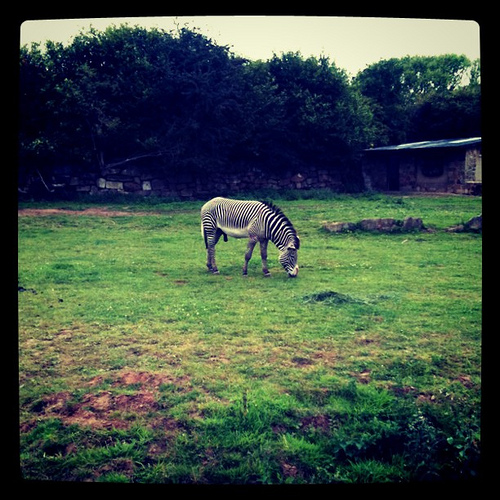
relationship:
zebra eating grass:
[199, 194, 301, 277] [17, 199, 483, 485]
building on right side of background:
[361, 135, 484, 195] [18, 14, 484, 198]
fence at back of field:
[17, 160, 366, 200] [19, 201, 485, 485]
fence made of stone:
[17, 160, 366, 200] [18, 164, 363, 200]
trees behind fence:
[21, 23, 483, 170] [17, 160, 366, 200]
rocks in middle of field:
[322, 213, 483, 235] [19, 201, 485, 485]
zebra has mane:
[199, 194, 301, 277] [259, 197, 301, 249]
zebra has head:
[199, 194, 301, 277] [281, 240, 302, 280]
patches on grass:
[18, 324, 482, 484] [17, 199, 483, 485]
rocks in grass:
[322, 213, 483, 235] [17, 199, 483, 485]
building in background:
[361, 135, 484, 195] [18, 14, 484, 198]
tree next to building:
[407, 97, 483, 143] [361, 135, 484, 195]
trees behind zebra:
[21, 23, 483, 170] [199, 194, 301, 277]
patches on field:
[18, 324, 482, 484] [19, 201, 485, 485]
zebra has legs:
[199, 194, 301, 277] [202, 233, 272, 276]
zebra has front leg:
[199, 194, 301, 277] [258, 238, 272, 277]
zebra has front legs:
[199, 194, 301, 277] [242, 231, 272, 276]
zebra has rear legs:
[199, 194, 301, 277] [198, 209, 219, 273]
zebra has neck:
[199, 194, 301, 277] [264, 203, 299, 250]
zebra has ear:
[199, 194, 301, 277] [285, 243, 298, 253]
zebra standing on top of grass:
[199, 194, 301, 277] [17, 199, 483, 485]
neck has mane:
[264, 203, 299, 250] [259, 197, 301, 249]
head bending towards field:
[281, 240, 302, 280] [19, 201, 485, 485]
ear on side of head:
[285, 243, 298, 253] [281, 240, 302, 280]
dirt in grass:
[18, 370, 196, 459] [17, 199, 483, 485]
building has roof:
[361, 135, 484, 195] [365, 137, 482, 151]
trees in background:
[21, 23, 483, 170] [18, 14, 484, 198]